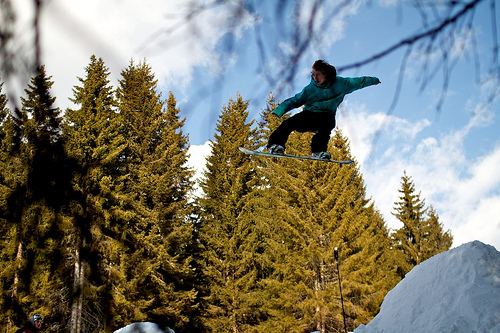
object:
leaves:
[190, 195, 229, 224]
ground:
[337, 240, 500, 333]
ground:
[105, 319, 183, 331]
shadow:
[16, 114, 128, 209]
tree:
[6, 55, 144, 320]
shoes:
[268, 145, 286, 156]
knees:
[278, 117, 299, 133]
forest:
[0, 54, 452, 332]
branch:
[358, 0, 499, 86]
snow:
[405, 266, 499, 303]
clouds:
[1, 2, 498, 255]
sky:
[1, 1, 498, 247]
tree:
[194, 88, 276, 331]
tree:
[61, 55, 235, 325]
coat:
[271, 75, 383, 118]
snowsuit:
[266, 76, 383, 152]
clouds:
[366, 137, 450, 187]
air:
[416, 94, 457, 129]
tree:
[135, 2, 498, 104]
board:
[238, 144, 354, 166]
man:
[268, 60, 382, 162]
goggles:
[310, 71, 327, 77]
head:
[311, 59, 337, 85]